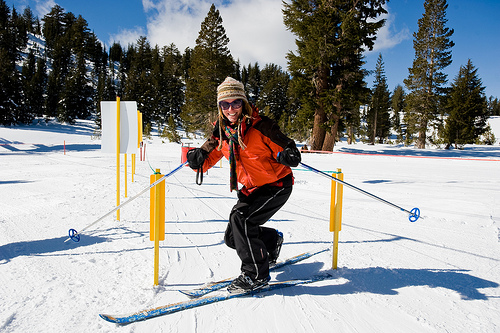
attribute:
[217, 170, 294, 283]
pants — black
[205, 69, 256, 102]
hat — knitted, ski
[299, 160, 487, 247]
pole — blue, ski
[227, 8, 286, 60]
clouds — white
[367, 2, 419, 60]
clouds — white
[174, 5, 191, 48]
clouds — white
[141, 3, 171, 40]
clouds — white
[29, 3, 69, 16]
clouds — white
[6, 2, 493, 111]
sky — blue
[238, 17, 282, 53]
clouds — white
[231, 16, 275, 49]
clouds — white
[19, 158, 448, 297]
snow — white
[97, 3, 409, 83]
cloud — white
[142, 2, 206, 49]
clouds — white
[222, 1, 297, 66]
clouds — white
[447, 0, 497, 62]
sky — blue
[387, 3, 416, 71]
sky — blue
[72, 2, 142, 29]
sky — blue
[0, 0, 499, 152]
trees — tall, green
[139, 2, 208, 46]
cloud — white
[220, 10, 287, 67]
cloud — white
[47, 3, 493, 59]
sky — blue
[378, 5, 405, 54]
cloud — white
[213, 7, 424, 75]
clouds — white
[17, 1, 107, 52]
cloud — white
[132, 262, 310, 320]
skis — blue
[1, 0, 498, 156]
evergreen trees — tall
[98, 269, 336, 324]
ski — blue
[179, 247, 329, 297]
ski — blue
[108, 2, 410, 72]
cloud — white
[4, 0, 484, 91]
sky — blue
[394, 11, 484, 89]
sky — blue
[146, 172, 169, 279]
post — yellow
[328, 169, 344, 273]
post — yellow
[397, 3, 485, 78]
sky — blue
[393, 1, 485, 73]
sky — blue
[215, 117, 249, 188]
scarf — multi-colored